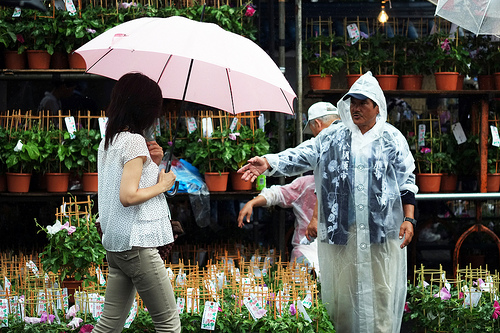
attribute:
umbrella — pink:
[69, 12, 304, 199]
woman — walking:
[91, 67, 189, 331]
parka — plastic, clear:
[261, 69, 418, 332]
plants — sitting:
[3, 242, 499, 332]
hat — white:
[298, 97, 339, 135]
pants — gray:
[86, 231, 183, 331]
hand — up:
[233, 154, 270, 186]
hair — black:
[103, 69, 165, 150]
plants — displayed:
[302, 11, 499, 90]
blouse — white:
[92, 127, 179, 249]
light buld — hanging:
[374, 1, 390, 25]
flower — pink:
[438, 37, 453, 53]